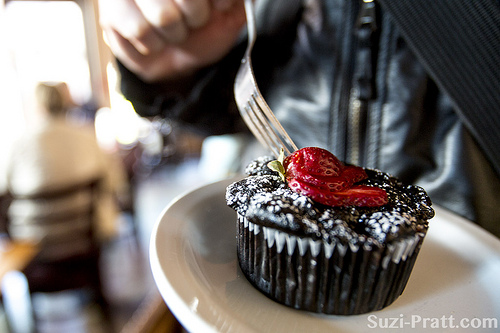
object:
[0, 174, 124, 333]
wooden chair